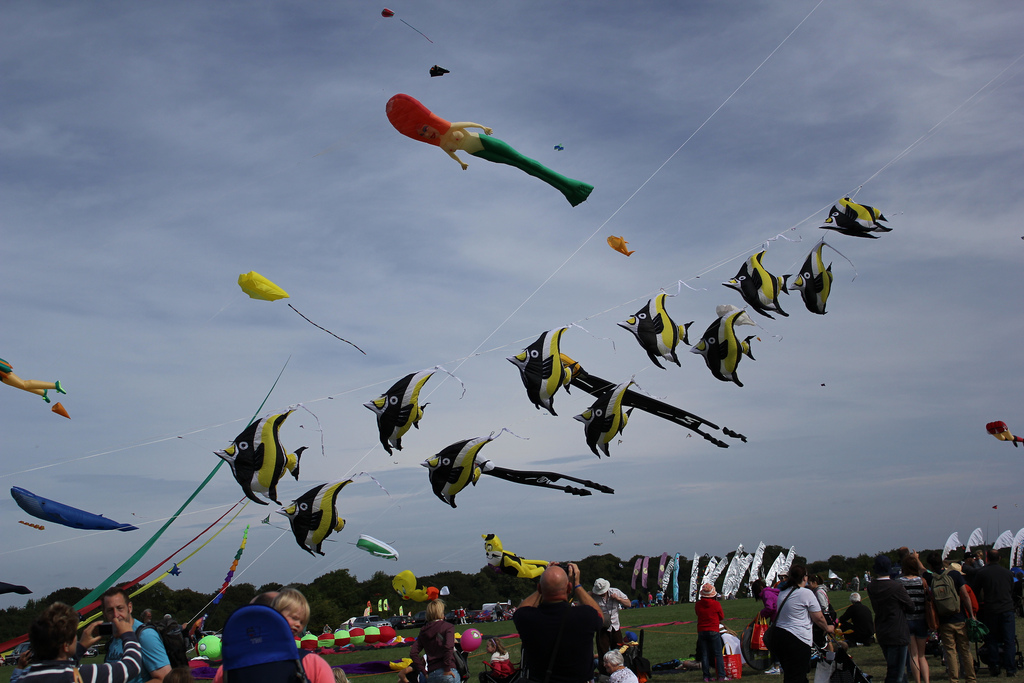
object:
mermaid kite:
[384, 94, 590, 207]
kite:
[819, 193, 893, 239]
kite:
[213, 406, 309, 506]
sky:
[0, 0, 1024, 598]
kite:
[276, 474, 358, 558]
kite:
[362, 370, 439, 456]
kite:
[421, 430, 615, 508]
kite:
[507, 326, 578, 416]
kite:
[572, 374, 637, 459]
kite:
[618, 293, 695, 370]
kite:
[692, 309, 757, 387]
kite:
[239, 269, 368, 355]